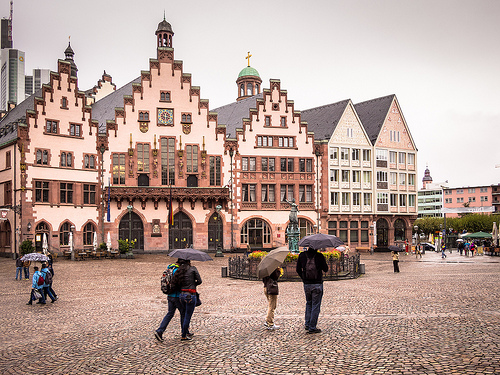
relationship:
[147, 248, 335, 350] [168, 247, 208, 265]
people under umbrella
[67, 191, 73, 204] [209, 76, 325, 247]
windows on building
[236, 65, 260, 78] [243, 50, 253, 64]
dome has cross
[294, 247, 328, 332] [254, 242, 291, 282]
people holding umbrella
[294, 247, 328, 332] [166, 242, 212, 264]
people holding umbrella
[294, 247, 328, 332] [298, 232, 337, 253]
people holding umbrella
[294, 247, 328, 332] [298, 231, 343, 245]
people holding umbrella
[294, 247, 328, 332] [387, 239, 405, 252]
people holding umbrella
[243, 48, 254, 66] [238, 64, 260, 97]
cross on top of tower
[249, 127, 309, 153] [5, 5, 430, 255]
windows on building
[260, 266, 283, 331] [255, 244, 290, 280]
woman carry umbrella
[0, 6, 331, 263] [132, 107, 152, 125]
building has window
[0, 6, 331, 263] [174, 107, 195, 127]
building has window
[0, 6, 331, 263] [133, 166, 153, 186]
building has window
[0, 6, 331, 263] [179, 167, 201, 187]
building has window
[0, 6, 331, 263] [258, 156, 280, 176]
building has window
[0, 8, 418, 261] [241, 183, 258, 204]
building has window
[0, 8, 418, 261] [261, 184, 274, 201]
building has window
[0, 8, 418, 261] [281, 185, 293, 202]
building has window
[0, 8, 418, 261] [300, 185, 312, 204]
building has window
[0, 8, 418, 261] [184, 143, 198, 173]
building has window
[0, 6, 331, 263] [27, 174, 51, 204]
building has window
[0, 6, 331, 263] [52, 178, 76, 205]
building has window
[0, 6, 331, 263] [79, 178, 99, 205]
building has window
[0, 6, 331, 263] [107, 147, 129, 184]
building has window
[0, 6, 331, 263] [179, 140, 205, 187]
building has window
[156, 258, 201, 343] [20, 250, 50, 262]
couple carrying umbrella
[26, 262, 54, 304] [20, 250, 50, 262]
couple carrying umbrella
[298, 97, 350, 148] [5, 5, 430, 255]
roof on a building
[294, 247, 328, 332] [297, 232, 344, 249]
people holding umbrella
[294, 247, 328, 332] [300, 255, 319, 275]
people has backpack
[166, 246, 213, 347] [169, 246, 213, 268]
woman carrying umbrella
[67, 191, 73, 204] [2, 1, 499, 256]
windows on building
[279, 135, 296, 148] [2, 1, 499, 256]
windows on building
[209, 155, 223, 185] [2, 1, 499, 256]
windows on building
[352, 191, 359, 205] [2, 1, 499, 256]
windows on building